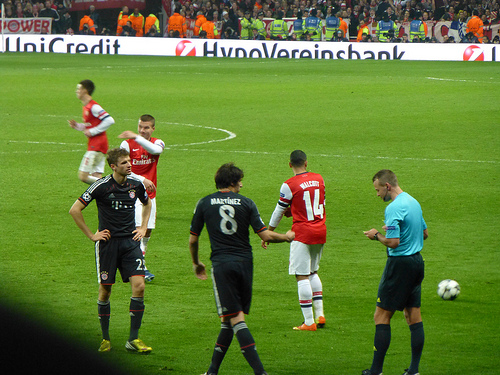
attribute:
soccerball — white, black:
[436, 276, 465, 302]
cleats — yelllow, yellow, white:
[99, 336, 156, 356]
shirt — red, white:
[274, 171, 336, 245]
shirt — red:
[78, 102, 116, 156]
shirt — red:
[117, 133, 167, 200]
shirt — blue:
[183, 190, 269, 256]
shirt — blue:
[74, 174, 158, 242]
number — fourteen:
[300, 188, 327, 222]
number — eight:
[212, 199, 240, 240]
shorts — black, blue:
[206, 253, 256, 318]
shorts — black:
[91, 236, 148, 280]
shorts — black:
[372, 249, 426, 314]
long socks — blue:
[207, 322, 275, 375]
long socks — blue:
[94, 298, 151, 341]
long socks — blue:
[370, 323, 428, 375]